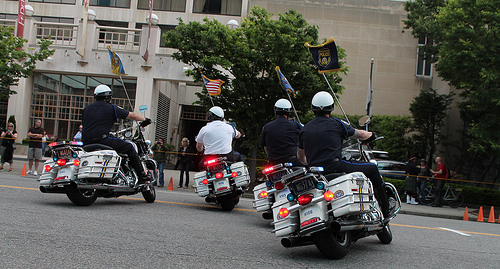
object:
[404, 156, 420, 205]
person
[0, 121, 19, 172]
person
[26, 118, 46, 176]
person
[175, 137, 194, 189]
person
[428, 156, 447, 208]
person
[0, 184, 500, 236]
yellow line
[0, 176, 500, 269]
road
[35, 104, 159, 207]
motorcycle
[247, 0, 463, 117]
wall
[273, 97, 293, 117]
helmet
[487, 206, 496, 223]
cone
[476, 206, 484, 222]
cone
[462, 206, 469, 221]
cone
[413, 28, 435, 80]
window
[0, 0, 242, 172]
white building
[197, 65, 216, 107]
pole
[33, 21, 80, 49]
railing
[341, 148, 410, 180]
vehicle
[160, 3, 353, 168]
bush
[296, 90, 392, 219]
police officer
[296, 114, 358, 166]
shirt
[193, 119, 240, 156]
shirt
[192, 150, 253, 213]
motorcycle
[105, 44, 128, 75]
flag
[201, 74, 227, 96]
flag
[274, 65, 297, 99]
flag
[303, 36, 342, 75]
flag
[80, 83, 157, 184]
policeman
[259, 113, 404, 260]
motorcycle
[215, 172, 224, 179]
brakelights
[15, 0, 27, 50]
sign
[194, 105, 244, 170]
policeman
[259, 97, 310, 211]
policeman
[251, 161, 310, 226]
motorcycle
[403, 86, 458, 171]
tree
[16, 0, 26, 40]
flag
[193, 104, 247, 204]
man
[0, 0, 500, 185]
building